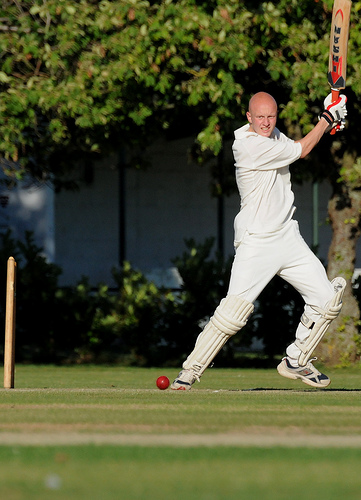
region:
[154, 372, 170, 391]
A small red ball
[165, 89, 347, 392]
A man playing cricket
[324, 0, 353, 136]
A large wooden cricket bat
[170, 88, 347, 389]
A bald man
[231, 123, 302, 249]
A white polo shirt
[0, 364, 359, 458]
Closely mowed green grass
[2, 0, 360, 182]
lush, green tree foliage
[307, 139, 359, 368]
A large tree trunk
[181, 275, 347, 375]
white shin guards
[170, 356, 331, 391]
White tennis shoes with red and blue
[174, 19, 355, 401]
Man playing cricket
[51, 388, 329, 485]
Green grass on a cricket field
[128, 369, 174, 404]
Red ball on the ground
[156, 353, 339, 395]
Pair of tennis shoes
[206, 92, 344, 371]
A man wearing all white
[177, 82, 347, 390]
A man wearing pads on his legs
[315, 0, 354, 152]
Bat for playing cricket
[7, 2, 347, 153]
Trees with green leaves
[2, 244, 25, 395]
Cricket wicket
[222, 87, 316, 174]
Man with a bald head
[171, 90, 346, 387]
the tall bald man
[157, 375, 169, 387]
the small red ball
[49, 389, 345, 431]
the grass in front of the man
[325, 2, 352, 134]
the sports item in the man's hands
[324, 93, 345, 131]
the man's sports gloves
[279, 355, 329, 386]
the man's left shoe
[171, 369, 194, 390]
the man's right shoe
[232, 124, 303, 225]
the man's white shirt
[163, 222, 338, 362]
the man's white pants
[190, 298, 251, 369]
the man's right shin and knee guards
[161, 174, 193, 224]
part of a wall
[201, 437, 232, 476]
part of a green ground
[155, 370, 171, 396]
part of a ball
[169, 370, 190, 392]
edge of a shoe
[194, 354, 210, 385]
part of a guard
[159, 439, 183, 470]
part of a green field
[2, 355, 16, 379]
part of a pole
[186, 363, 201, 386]
part of a lace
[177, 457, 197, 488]
part of a grass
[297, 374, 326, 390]
edge of a shoe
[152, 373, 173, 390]
a ball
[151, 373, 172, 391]
the ball is red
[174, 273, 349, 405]
the man wears shin guards on his legs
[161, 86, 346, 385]
a man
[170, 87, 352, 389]
a man wearing white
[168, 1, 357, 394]
the man is holding a wood paddle with both hands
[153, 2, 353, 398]
the man is swinging the paddle at a ball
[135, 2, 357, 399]
the man is getting ready to swing the paddle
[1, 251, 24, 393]
a wooden post is in the grass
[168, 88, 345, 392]
the man is bald